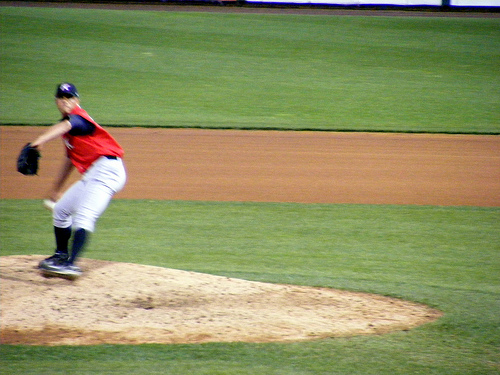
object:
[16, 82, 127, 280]
man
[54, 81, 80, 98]
hat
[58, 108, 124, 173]
shirt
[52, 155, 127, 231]
pants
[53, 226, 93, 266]
socks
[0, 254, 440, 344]
mound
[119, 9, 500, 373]
field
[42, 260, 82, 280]
foot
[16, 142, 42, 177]
glove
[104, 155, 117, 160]
belt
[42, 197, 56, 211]
ball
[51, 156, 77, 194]
arm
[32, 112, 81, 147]
arm